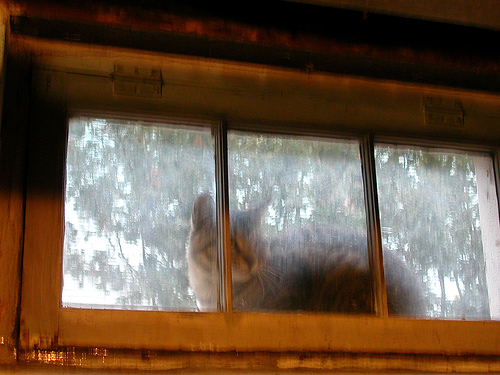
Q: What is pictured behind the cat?
A: A tree.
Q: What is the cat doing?
A: Looking through a window.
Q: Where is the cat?
A: Outside the window.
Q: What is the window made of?
A: Glass.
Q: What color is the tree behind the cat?
A: Mostly green.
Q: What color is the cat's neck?
A: White.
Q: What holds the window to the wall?
A: Hinges.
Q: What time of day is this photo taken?
A: In the daytime.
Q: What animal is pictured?
A: A house cat.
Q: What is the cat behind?
A: Window.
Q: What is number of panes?
A: Three.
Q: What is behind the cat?
A: Trees.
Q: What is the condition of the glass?
A: Smudge, dirty.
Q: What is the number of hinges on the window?
A: Two.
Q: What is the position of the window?
A: Closed.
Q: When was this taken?
A: Maybe late afternoon.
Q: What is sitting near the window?
A: A cat.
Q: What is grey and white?
A: The cat.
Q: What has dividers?
A: The window.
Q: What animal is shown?
A: A cat.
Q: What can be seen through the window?
A: A cat.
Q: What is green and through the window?
A: Trees.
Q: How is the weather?
A: Clear.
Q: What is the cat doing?
A: Laying by the window.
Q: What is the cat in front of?
A: A window.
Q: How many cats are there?
A: One.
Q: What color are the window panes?
A: Clear.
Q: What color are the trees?
A: Green.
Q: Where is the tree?
A: Behind the cat.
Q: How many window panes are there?
A: Three.